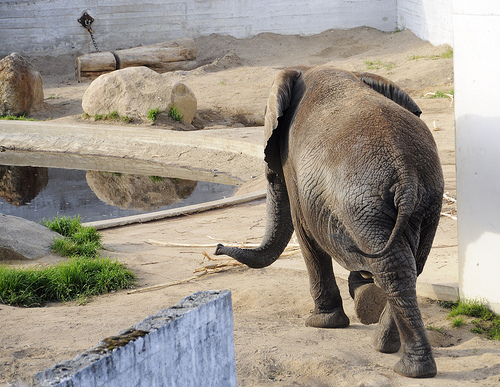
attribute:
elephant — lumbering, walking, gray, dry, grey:
[212, 70, 461, 376]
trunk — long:
[211, 166, 296, 289]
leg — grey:
[366, 236, 456, 381]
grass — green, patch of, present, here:
[4, 267, 161, 310]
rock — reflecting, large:
[76, 64, 192, 152]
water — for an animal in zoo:
[11, 141, 227, 234]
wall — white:
[120, 9, 333, 28]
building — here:
[12, 13, 498, 154]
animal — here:
[229, 44, 462, 386]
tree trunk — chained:
[62, 30, 207, 71]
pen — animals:
[4, 1, 449, 377]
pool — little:
[4, 110, 286, 240]